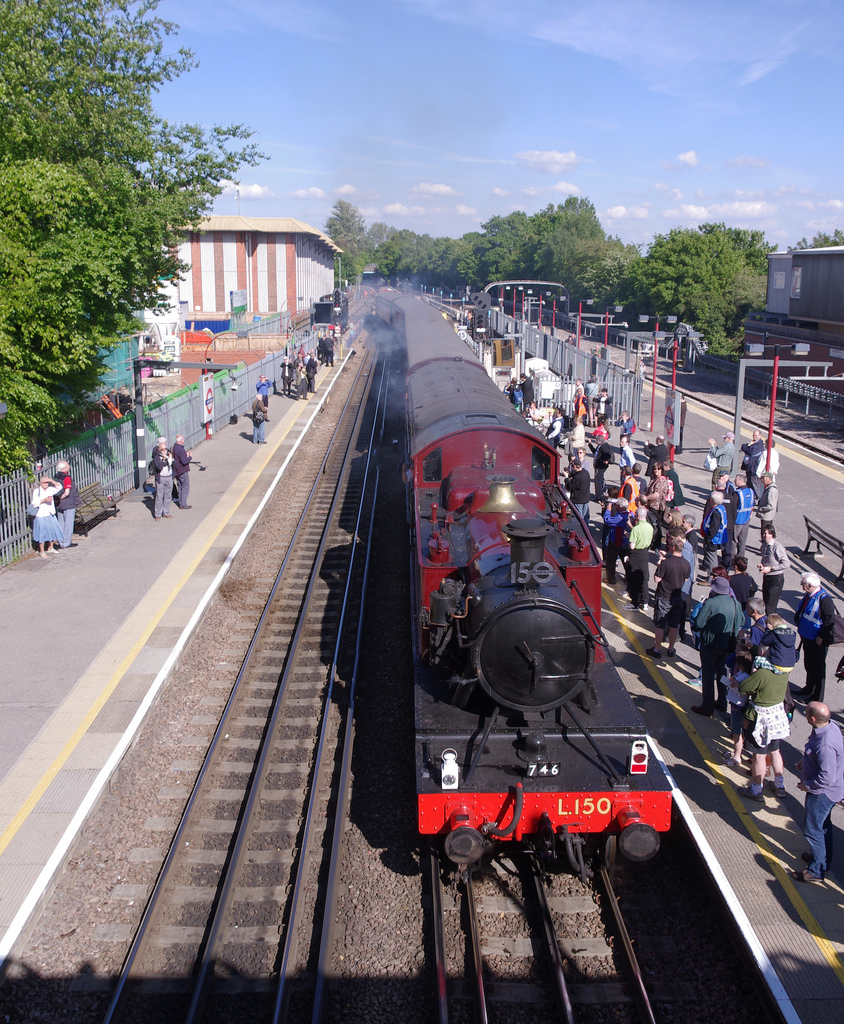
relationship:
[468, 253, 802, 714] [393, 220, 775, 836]
people on platform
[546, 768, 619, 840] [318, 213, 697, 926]
number in front of train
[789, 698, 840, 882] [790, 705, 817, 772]
man wearing shirt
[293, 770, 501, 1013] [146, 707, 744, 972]
gravel in between tracks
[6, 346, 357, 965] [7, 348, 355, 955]
line on edge of platform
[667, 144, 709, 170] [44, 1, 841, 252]
cloud in sky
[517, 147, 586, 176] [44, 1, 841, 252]
cloud in sky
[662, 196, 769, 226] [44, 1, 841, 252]
cloud in sky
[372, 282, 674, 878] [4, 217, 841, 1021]
train at station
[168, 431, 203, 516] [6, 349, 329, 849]
person waiting behind line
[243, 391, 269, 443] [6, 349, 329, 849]
person waiting behind line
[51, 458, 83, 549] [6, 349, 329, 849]
person waiting behind line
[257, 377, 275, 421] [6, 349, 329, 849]
person waiting behind line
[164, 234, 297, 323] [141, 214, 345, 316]
stripes on building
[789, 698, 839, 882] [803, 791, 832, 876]
man wearing jeans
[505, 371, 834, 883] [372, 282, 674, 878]
people waiting to get train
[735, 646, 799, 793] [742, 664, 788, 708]
person wearing shirt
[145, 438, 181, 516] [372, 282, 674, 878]
person waiting for train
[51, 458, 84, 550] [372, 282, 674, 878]
person waiting for train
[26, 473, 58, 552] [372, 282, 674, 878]
person waiting for train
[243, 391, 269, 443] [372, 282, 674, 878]
person waiting for train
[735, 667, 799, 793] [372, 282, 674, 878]
person waiting for train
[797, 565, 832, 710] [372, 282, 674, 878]
people waiting for train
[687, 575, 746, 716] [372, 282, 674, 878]
person waiting for train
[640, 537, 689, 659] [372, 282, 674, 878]
person waiting for train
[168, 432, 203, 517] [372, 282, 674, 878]
person waiting for train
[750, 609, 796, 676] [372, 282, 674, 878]
person waiting for train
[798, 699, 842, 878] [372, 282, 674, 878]
person waiting for train